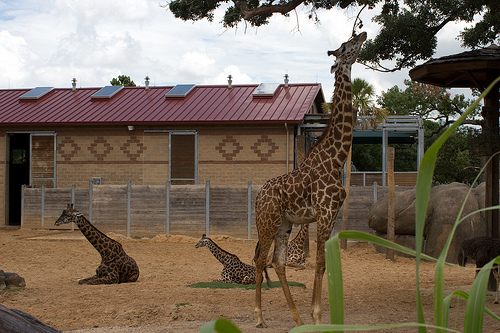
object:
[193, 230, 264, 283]
giraffe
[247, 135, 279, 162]
pattern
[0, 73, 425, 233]
building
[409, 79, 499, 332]
leaves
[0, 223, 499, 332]
ground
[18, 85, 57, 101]
panels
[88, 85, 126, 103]
panels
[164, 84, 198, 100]
panels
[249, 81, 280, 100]
panels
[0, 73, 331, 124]
roof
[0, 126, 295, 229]
wall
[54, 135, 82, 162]
pattern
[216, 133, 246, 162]
pattern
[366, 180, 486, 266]
rock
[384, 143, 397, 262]
post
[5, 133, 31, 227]
door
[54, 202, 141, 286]
giraffe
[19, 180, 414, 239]
fence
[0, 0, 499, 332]
pen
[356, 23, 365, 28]
leaf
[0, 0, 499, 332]
background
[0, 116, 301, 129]
edge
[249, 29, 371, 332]
giraffe